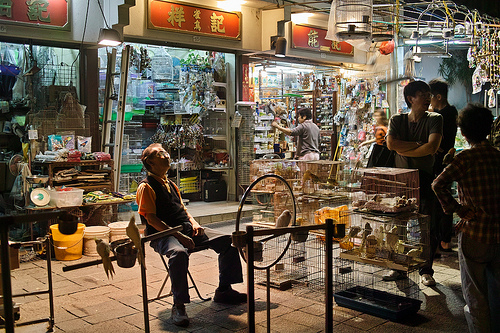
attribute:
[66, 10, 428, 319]
store — open pet 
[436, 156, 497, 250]
shirt — flannel 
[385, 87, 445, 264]
person — shopping 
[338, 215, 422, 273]
cage — full of birds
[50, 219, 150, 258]
row — of plastic buckets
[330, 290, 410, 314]
bottom — blue